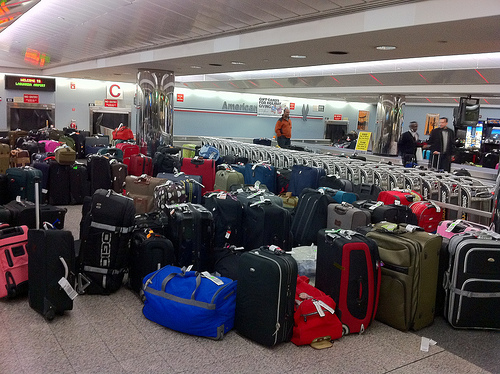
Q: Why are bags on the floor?
A: To be claimed.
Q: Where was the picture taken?
A: At an airport.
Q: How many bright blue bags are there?
A: One.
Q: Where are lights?
A: On the ceiling.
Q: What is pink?
A: Bag on left.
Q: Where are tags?
A: On the bags.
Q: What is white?
A: Tags on bags.